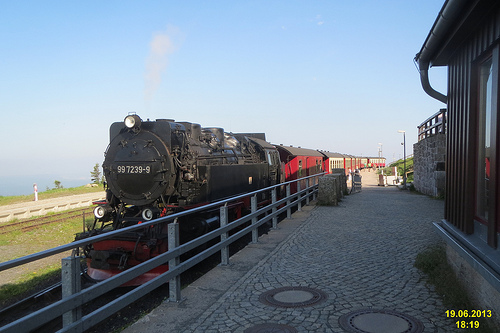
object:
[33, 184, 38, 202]
pole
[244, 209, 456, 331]
concrete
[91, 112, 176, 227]
train front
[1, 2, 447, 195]
blue sky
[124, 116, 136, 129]
white horn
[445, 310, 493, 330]
timestamp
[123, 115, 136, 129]
light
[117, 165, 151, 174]
numbers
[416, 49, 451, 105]
pipe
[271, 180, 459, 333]
ground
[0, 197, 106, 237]
grass tracks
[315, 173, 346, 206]
block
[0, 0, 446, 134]
clouds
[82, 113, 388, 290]
car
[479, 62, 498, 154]
window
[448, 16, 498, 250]
front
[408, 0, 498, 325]
building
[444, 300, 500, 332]
corner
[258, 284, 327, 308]
designs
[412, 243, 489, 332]
shrubbery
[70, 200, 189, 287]
engine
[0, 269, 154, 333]
tracks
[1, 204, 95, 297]
grass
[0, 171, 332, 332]
fence